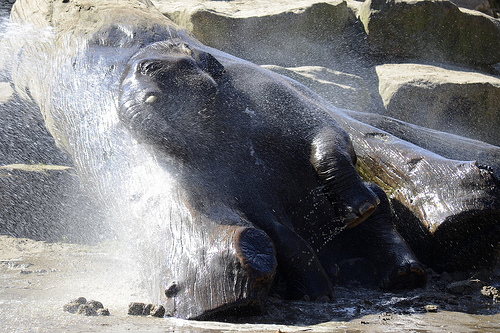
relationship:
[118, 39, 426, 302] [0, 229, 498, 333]
elephant on ground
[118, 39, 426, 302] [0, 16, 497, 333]
elephant in water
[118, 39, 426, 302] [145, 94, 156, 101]
elephant has a tusky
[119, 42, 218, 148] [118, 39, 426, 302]
head on elephant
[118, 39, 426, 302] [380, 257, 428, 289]
elephant has a back left foot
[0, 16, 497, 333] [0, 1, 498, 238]
water sprayed on rocks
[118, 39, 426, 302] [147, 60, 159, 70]
elephant has a left eye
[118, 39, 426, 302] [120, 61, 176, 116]
elephant has a face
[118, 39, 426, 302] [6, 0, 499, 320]
elephant between log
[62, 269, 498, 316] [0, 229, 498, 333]
rocks on ground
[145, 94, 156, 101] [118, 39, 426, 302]
tusky on side of elephant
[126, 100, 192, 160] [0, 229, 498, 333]
trunk above ground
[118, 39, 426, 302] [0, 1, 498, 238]
elephant leaning on rocks